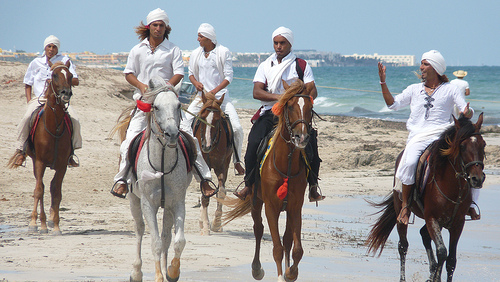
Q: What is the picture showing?
A: It is showing a beach.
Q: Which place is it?
A: It is a beach.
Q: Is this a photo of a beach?
A: Yes, it is showing a beach.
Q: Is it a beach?
A: Yes, it is a beach.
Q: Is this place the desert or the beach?
A: It is the beach.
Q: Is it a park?
A: No, it is a beach.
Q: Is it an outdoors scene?
A: Yes, it is outdoors.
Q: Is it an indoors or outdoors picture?
A: It is outdoors.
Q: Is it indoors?
A: No, it is outdoors.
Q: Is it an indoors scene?
A: No, it is outdoors.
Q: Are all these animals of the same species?
A: Yes, all the animals are horses.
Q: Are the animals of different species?
A: No, all the animals are horses.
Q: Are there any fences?
A: No, there are no fences.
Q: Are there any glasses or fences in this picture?
A: No, there are no fences or glasses.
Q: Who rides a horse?
A: The man rides a horse.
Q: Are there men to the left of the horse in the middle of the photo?
A: Yes, there is a man to the left of the horse.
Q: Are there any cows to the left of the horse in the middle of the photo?
A: No, there is a man to the left of the horse.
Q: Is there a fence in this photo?
A: No, there are no fences.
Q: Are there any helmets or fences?
A: No, there are no fences or helmets.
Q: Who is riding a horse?
A: The man is riding a horse.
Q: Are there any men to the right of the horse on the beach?
A: Yes, there is a man to the right of the horse.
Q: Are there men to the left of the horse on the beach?
A: No, the man is to the right of the horse.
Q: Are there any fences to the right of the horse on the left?
A: No, there is a man to the right of the horse.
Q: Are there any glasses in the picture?
A: No, there are no glasses.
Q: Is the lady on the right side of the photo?
A: Yes, the lady is on the right of the image.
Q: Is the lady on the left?
A: No, the lady is on the right of the image.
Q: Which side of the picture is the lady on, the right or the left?
A: The lady is on the right of the image.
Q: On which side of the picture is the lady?
A: The lady is on the right of the image.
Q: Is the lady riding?
A: Yes, the lady is riding.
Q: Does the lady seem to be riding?
A: Yes, the lady is riding.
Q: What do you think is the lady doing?
A: The lady is riding.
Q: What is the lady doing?
A: The lady is riding.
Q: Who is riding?
A: The lady is riding.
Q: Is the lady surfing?
A: No, the lady is riding.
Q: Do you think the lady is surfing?
A: No, the lady is riding.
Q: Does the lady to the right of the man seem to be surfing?
A: No, the lady is riding.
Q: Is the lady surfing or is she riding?
A: The lady is riding.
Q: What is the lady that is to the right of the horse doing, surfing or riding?
A: The lady is riding.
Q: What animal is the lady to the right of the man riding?
A: The lady is riding a horse.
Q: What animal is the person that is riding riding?
A: The lady is riding a horse.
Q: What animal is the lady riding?
A: The lady is riding a horse.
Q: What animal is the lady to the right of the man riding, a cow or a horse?
A: The lady is riding a horse.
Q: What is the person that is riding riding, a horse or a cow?
A: The lady is riding a horse.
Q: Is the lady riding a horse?
A: Yes, the lady is riding a horse.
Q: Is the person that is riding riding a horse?
A: Yes, the lady is riding a horse.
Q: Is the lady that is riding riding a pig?
A: No, the lady is riding a horse.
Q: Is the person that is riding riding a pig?
A: No, the lady is riding a horse.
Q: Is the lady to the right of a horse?
A: Yes, the lady is to the right of a horse.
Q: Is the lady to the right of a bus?
A: No, the lady is to the right of a horse.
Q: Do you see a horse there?
A: Yes, there is a horse.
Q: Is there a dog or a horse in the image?
A: Yes, there is a horse.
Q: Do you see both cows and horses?
A: No, there is a horse but no cows.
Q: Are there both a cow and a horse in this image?
A: No, there is a horse but no cows.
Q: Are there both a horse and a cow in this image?
A: No, there is a horse but no cows.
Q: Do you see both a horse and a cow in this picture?
A: No, there is a horse but no cows.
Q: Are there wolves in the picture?
A: No, there are no wolves.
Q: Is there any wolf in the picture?
A: No, there are no wolves.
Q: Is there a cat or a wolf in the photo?
A: No, there are no wolves or cats.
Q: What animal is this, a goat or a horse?
A: This is a horse.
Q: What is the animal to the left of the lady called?
A: The animal is a horse.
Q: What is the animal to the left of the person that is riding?
A: The animal is a horse.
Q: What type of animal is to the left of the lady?
A: The animal is a horse.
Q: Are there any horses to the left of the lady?
A: Yes, there is a horse to the left of the lady.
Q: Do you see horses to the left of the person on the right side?
A: Yes, there is a horse to the left of the lady.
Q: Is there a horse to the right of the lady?
A: No, the horse is to the left of the lady.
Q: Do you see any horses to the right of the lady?
A: No, the horse is to the left of the lady.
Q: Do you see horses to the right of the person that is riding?
A: No, the horse is to the left of the lady.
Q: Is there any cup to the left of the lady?
A: No, there is a horse to the left of the lady.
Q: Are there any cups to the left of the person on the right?
A: No, there is a horse to the left of the lady.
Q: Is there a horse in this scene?
A: Yes, there is a horse.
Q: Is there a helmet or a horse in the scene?
A: Yes, there is a horse.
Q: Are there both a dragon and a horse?
A: No, there is a horse but no dragons.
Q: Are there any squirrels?
A: No, there are no squirrels.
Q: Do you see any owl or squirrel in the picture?
A: No, there are no squirrels or owls.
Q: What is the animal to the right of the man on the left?
A: The animal is a horse.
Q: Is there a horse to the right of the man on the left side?
A: Yes, there is a horse to the right of the man.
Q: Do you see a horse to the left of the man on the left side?
A: No, the horse is to the right of the man.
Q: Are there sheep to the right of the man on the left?
A: No, there is a horse to the right of the man.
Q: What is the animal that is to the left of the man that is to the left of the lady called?
A: The animal is a horse.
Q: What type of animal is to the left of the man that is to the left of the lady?
A: The animal is a horse.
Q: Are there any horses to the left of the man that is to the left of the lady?
A: Yes, there is a horse to the left of the man.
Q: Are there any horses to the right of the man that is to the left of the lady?
A: No, the horse is to the left of the man.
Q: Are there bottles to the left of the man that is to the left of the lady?
A: No, there is a horse to the left of the man.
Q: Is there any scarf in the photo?
A: Yes, there is a scarf.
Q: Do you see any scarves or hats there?
A: Yes, there is a scarf.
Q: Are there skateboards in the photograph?
A: No, there are no skateboards.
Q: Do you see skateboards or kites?
A: No, there are no skateboards or kites.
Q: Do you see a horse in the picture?
A: Yes, there is a horse.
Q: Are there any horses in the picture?
A: Yes, there is a horse.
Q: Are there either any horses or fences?
A: Yes, there is a horse.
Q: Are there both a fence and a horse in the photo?
A: No, there is a horse but no fences.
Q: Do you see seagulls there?
A: No, there are no seagulls.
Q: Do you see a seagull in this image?
A: No, there are no seagulls.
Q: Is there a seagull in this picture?
A: No, there are no seagulls.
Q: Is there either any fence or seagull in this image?
A: No, there are no seagulls or fences.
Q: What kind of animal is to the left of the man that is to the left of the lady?
A: The animal is a horse.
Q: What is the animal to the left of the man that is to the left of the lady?
A: The animal is a horse.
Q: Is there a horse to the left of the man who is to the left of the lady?
A: Yes, there is a horse to the left of the man.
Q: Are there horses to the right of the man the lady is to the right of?
A: No, the horse is to the left of the man.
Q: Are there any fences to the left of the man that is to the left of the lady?
A: No, there is a horse to the left of the man.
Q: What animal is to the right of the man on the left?
A: The animal is a horse.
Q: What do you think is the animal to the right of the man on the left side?
A: The animal is a horse.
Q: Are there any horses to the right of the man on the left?
A: Yes, there is a horse to the right of the man.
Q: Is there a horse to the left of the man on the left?
A: No, the horse is to the right of the man.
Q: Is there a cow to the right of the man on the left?
A: No, there is a horse to the right of the man.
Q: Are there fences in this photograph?
A: No, there are no fences.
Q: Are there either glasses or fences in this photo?
A: No, there are no fences or glasses.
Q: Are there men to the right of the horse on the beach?
A: Yes, there is a man to the right of the horse.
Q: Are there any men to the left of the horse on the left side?
A: No, the man is to the right of the horse.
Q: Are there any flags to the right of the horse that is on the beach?
A: No, there is a man to the right of the horse.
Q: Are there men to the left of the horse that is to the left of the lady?
A: Yes, there is a man to the left of the horse.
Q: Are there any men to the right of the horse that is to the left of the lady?
A: No, the man is to the left of the horse.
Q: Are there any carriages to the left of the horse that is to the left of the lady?
A: No, there is a man to the left of the horse.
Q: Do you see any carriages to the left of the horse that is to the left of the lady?
A: No, there is a man to the left of the horse.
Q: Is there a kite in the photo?
A: No, there are no kites.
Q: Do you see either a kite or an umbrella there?
A: No, there are no kites or umbrellas.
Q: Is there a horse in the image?
A: Yes, there is a horse.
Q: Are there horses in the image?
A: Yes, there is a horse.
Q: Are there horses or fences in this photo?
A: Yes, there is a horse.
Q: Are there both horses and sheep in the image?
A: No, there is a horse but no sheep.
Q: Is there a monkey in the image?
A: No, there are no monkeys.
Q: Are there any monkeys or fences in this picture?
A: No, there are no monkeys or fences.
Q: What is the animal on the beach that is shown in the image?
A: The animal is a horse.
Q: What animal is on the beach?
A: The animal is a horse.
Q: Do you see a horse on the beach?
A: Yes, there is a horse on the beach.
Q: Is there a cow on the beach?
A: No, there is a horse on the beach.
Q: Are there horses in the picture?
A: Yes, there is a horse.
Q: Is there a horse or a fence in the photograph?
A: Yes, there is a horse.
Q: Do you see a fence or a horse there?
A: Yes, there is a horse.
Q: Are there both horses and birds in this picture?
A: No, there is a horse but no birds.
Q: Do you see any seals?
A: No, there are no seals.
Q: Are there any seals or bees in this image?
A: No, there are no seals or bees.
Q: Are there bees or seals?
A: No, there are no seals or bees.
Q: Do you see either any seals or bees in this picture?
A: No, there are no seals or bees.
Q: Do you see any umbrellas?
A: No, there are no umbrellas.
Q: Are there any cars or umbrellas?
A: No, there are no umbrellas or cars.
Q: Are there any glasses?
A: No, there are no glasses.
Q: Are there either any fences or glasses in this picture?
A: No, there are no glasses or fences.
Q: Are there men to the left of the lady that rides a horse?
A: Yes, there is a man to the left of the lady.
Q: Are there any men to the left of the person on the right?
A: Yes, there is a man to the left of the lady.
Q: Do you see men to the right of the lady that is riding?
A: No, the man is to the left of the lady.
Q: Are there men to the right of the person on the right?
A: No, the man is to the left of the lady.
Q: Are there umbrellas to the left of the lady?
A: No, there is a man to the left of the lady.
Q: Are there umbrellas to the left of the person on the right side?
A: No, there is a man to the left of the lady.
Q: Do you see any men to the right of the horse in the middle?
A: Yes, there is a man to the right of the horse.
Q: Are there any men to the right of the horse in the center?
A: Yes, there is a man to the right of the horse.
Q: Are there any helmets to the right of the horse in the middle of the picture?
A: No, there is a man to the right of the horse.